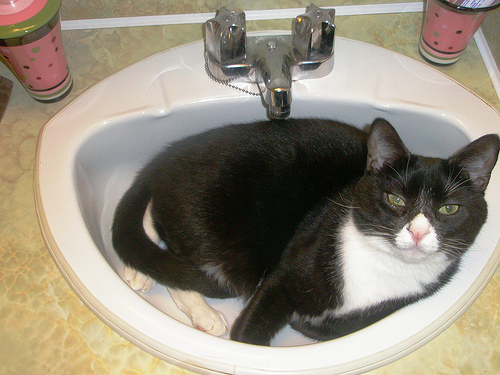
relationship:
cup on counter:
[0, 0, 81, 106] [16, 30, 235, 337]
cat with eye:
[105, 108, 499, 350] [377, 185, 410, 214]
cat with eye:
[105, 108, 499, 350] [425, 196, 465, 226]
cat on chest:
[111, 116, 499, 346] [324, 228, 425, 314]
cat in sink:
[105, 108, 499, 350] [59, 125, 139, 249]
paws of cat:
[166, 269, 267, 343] [113, 107, 492, 287]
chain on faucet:
[204, 55, 262, 97] [254, 33, 296, 123]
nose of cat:
[410, 216, 427, 246] [105, 108, 499, 350]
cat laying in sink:
[105, 108, 499, 350] [61, 11, 495, 374]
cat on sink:
[105, 108, 499, 350] [61, 11, 495, 374]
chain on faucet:
[202, 60, 273, 102] [203, 3, 335, 120]